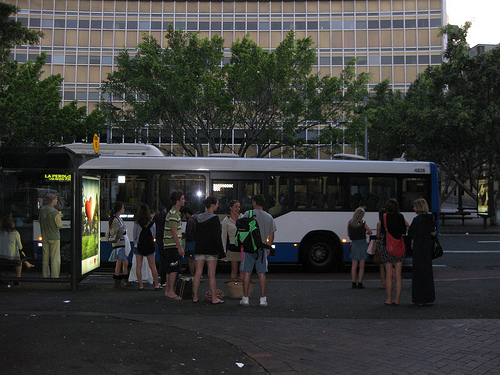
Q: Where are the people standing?
A: Bus stop.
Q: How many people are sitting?
A: 1.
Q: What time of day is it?
A: Evening.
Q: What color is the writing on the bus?
A: Green.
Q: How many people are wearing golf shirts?
A: 1.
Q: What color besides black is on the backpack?
A: Neon Green.